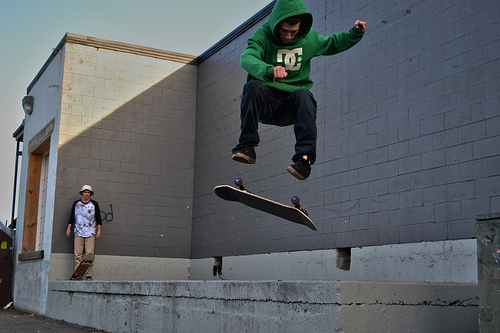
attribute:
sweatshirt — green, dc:
[235, 1, 368, 99]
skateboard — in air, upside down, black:
[210, 175, 321, 233]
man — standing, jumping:
[63, 183, 106, 287]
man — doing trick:
[230, 2, 371, 181]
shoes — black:
[281, 153, 314, 183]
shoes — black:
[230, 142, 263, 169]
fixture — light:
[18, 94, 37, 117]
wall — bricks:
[43, 37, 202, 321]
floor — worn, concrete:
[51, 274, 476, 310]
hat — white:
[75, 183, 97, 195]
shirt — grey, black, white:
[65, 196, 104, 241]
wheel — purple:
[232, 175, 245, 185]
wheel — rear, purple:
[288, 194, 301, 209]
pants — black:
[232, 77, 323, 168]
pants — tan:
[69, 232, 94, 281]